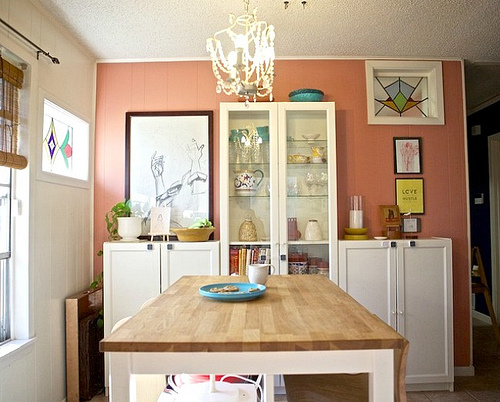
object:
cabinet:
[337, 238, 453, 393]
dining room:
[0, 0, 500, 400]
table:
[98, 275, 411, 400]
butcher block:
[97, 274, 407, 353]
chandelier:
[202, 0, 280, 109]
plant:
[104, 199, 134, 243]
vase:
[115, 214, 146, 242]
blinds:
[0, 57, 28, 171]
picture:
[123, 109, 216, 242]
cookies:
[222, 284, 240, 291]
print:
[391, 137, 425, 176]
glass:
[226, 110, 270, 273]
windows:
[283, 109, 330, 276]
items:
[232, 168, 266, 198]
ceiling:
[33, 0, 500, 62]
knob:
[397, 310, 405, 318]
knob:
[391, 310, 396, 319]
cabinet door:
[397, 240, 454, 384]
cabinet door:
[337, 239, 398, 329]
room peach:
[94, 56, 472, 370]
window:
[43, 98, 93, 183]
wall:
[0, 2, 97, 401]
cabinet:
[102, 241, 221, 400]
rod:
[0, 20, 61, 66]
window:
[0, 42, 31, 347]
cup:
[245, 261, 273, 285]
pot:
[113, 215, 147, 243]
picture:
[394, 177, 427, 218]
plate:
[197, 282, 269, 304]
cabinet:
[219, 100, 340, 284]